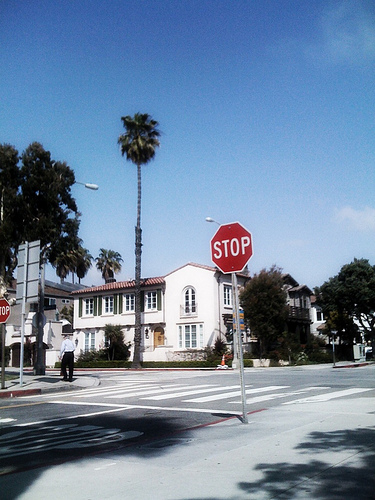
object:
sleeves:
[59, 337, 69, 356]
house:
[69, 275, 167, 364]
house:
[161, 261, 240, 368]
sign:
[207, 218, 252, 271]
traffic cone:
[219, 353, 227, 365]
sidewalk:
[292, 350, 373, 371]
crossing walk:
[17, 374, 373, 404]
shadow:
[233, 425, 361, 495]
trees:
[318, 256, 375, 364]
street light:
[71, 179, 100, 193]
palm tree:
[117, 112, 159, 369]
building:
[69, 263, 249, 361]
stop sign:
[209, 221, 251, 422]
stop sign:
[0, 297, 9, 389]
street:
[2, 363, 375, 500]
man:
[59, 330, 76, 382]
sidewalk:
[0, 374, 101, 391]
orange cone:
[219, 353, 226, 365]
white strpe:
[220, 356, 226, 361]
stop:
[0, 411, 144, 458]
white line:
[174, 384, 251, 400]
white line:
[181, 392, 239, 404]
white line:
[101, 382, 194, 396]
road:
[2, 363, 374, 500]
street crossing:
[12, 378, 362, 413]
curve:
[143, 365, 218, 374]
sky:
[0, 0, 375, 293]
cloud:
[0, 2, 375, 290]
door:
[152, 328, 162, 348]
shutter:
[94, 296, 105, 314]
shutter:
[113, 292, 123, 313]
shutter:
[154, 286, 161, 311]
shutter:
[156, 289, 163, 309]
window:
[79, 294, 96, 316]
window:
[125, 306, 129, 312]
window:
[124, 295, 134, 314]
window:
[144, 292, 158, 313]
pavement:
[1, 414, 145, 498]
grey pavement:
[0, 355, 375, 498]